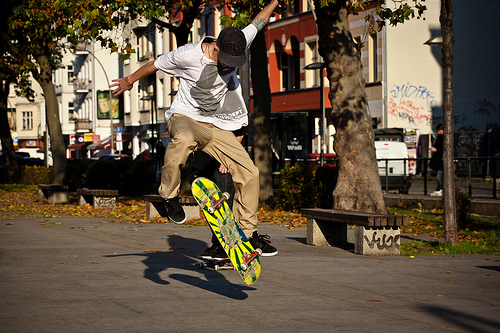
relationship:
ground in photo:
[27, 267, 495, 326] [28, 20, 481, 260]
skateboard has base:
[192, 184, 267, 286] [214, 202, 242, 247]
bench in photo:
[76, 178, 128, 217] [28, 20, 481, 260]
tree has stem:
[311, 13, 403, 221] [363, 14, 406, 38]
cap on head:
[221, 30, 252, 63] [207, 33, 253, 77]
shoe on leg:
[152, 194, 194, 231] [171, 145, 190, 197]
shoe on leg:
[236, 235, 278, 257] [221, 154, 271, 223]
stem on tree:
[100, 25, 132, 56] [16, 12, 89, 188]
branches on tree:
[37, 17, 116, 36] [16, 12, 89, 188]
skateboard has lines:
[192, 184, 267, 286] [220, 200, 225, 231]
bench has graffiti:
[302, 195, 432, 256] [369, 233, 410, 250]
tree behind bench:
[311, 13, 403, 221] [302, 195, 432, 256]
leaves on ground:
[19, 189, 54, 219] [27, 267, 495, 326]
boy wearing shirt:
[107, 18, 280, 258] [165, 51, 256, 114]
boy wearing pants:
[107, 18, 280, 258] [173, 120, 251, 209]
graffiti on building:
[391, 80, 438, 135] [282, 10, 498, 149]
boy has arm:
[107, 18, 280, 258] [252, 0, 278, 32]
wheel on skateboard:
[239, 261, 253, 278] [192, 184, 267, 286]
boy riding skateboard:
[165, 18, 248, 215] [192, 184, 267, 286]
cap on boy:
[214, 25, 247, 67] [165, 18, 248, 215]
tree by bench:
[311, 13, 403, 221] [76, 178, 128, 217]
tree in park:
[311, 13, 403, 221] [40, 86, 485, 303]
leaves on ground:
[47, 24, 70, 56] [27, 267, 495, 326]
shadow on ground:
[135, 219, 210, 303] [27, 267, 495, 326]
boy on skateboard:
[107, 18, 280, 258] [192, 184, 267, 286]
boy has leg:
[107, 18, 280, 258] [171, 145, 190, 197]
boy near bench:
[107, 18, 280, 258] [76, 178, 128, 217]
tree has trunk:
[311, 13, 403, 221] [321, 42, 383, 227]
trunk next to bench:
[321, 42, 383, 227] [302, 195, 432, 256]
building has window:
[282, 10, 498, 149] [300, 39, 322, 90]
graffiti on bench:
[391, 80, 438, 135] [302, 195, 432, 256]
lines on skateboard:
[220, 200, 225, 231] [192, 184, 267, 286]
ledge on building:
[274, 24, 329, 43] [282, 10, 498, 149]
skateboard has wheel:
[192, 184, 267, 286] [239, 261, 253, 278]